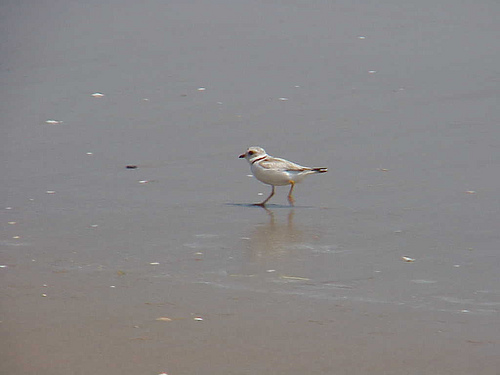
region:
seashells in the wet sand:
[143, 293, 224, 341]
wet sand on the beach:
[244, 291, 365, 354]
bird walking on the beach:
[225, 129, 335, 213]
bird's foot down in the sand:
[250, 198, 271, 209]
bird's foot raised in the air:
[282, 179, 299, 211]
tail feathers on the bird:
[304, 165, 329, 179]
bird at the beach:
[189, 108, 379, 245]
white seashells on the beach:
[36, 78, 118, 145]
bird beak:
[234, 148, 249, 169]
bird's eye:
[245, 145, 260, 158]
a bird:
[228, 145, 335, 205]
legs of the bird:
[254, 188, 299, 213]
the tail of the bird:
[314, 161, 326, 177]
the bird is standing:
[226, 138, 327, 203]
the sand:
[59, 235, 226, 370]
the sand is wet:
[351, 236, 466, 355]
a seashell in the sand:
[83, 83, 111, 101]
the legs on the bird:
[263, 188, 296, 205]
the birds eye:
[246, 148, 255, 157]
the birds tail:
[303, 165, 329, 180]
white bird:
[229, 124, 335, 217]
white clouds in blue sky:
[31, 40, 102, 114]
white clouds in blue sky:
[251, 59, 336, 108]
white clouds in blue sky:
[377, 6, 419, 69]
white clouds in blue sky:
[396, 46, 486, 103]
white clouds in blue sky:
[237, 17, 330, 67]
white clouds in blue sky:
[105, 14, 168, 53]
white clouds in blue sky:
[167, 13, 227, 62]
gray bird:
[220, 148, 310, 195]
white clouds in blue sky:
[16, 0, 54, 65]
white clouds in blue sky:
[170, 90, 206, 113]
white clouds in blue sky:
[361, 78, 427, 130]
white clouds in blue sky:
[231, 25, 289, 82]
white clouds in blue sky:
[82, 46, 164, 111]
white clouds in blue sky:
[82, 57, 131, 93]